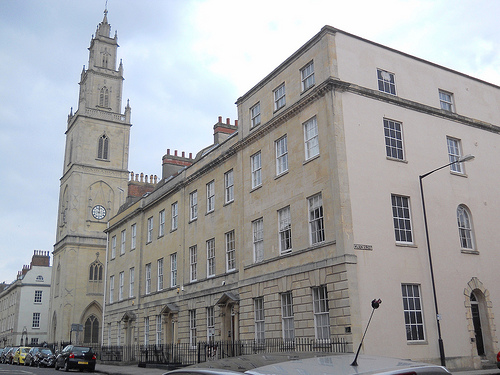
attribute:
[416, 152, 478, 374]
street light — black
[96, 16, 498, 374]
building — tall, beige, brown, tan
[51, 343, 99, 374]
vehicle — parked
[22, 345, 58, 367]
vehicle — parked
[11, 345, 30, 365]
vehicle — parked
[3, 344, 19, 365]
vehicle — parked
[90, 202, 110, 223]
clock — white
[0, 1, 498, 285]
sky — blue, white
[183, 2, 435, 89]
cloud — white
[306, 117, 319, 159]
curtains — white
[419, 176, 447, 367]
post — long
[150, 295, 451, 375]
car — silver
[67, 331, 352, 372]
fence — black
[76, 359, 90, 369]
license plate — yellow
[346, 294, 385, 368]
antenna — black